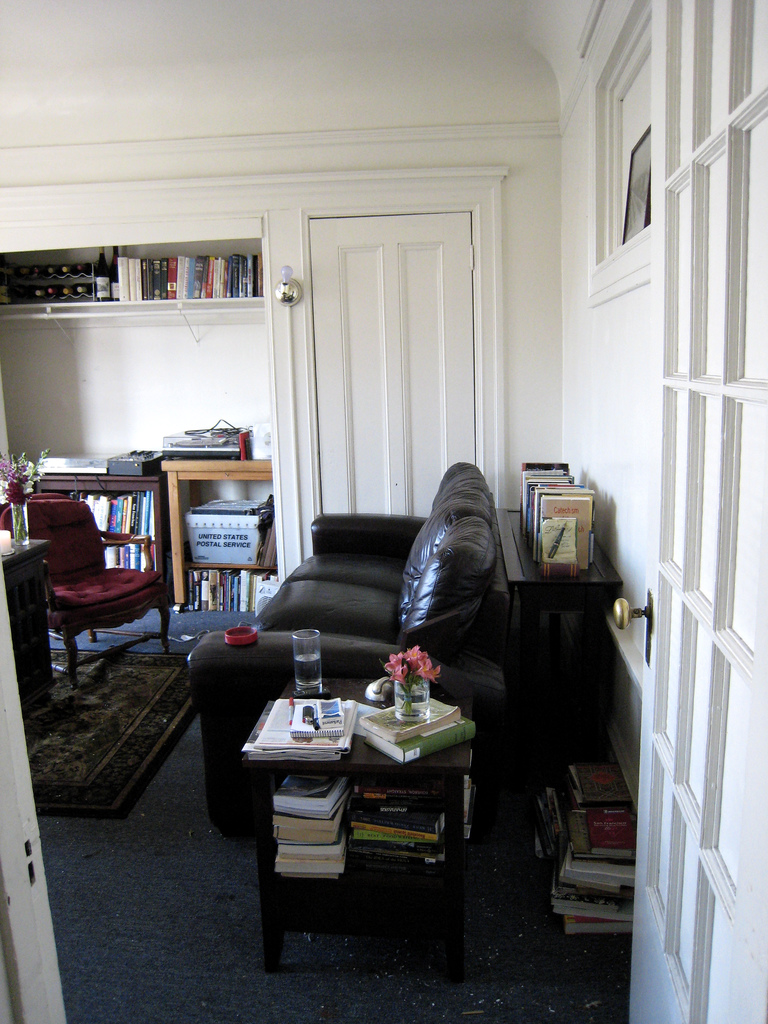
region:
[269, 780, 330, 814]
book on the shelf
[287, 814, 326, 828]
book on the shelf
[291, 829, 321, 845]
book on the shelf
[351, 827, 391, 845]
book on the shelf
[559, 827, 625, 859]
book on the shelf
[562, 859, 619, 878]
book on the shelf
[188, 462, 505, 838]
a black leather couch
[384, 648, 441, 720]
a small vase of flowers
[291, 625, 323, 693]
a clear glass of water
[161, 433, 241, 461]
an electronic record player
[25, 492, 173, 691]
a maroon end chair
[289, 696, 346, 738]
a white note pad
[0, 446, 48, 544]
a glass vase with flowers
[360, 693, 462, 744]
a trade paperback book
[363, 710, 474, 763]
a green hardback book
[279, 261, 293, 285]
a unlit light bulb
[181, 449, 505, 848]
Black leather couch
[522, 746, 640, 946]
Books stacked on floor behind end table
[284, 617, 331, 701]
Beverage glass on end table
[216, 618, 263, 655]
Ashtray on arm of leather couch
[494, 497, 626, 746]
Library table behind leather couch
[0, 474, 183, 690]
Red chair with wood frame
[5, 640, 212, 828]
Area rug in front of couch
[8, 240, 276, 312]
Books on inset shelf on wall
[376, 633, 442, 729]
Pink flowers in vase on end table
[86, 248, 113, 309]
a bottle for holding liquid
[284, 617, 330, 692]
a vessel made for drinking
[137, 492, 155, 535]
a book on a book shelf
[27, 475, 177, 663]
a chair that you sit in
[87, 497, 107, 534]
a book on a book shelf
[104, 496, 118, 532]
a book on a book shelf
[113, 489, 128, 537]
a book on a book shelf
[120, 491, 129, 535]
a book on a book shelf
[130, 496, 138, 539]
a book on a book shelf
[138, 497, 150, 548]
a book on a book shelf